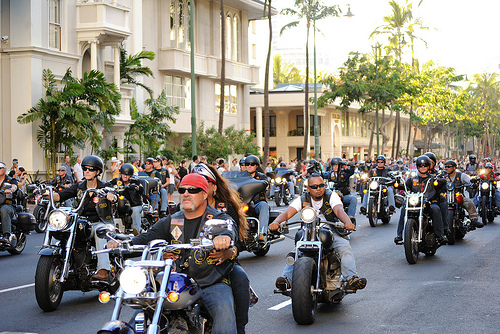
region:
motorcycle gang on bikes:
[32, 137, 496, 332]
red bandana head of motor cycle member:
[176, 170, 210, 191]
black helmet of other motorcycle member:
[79, 154, 104, 169]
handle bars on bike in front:
[94, 240, 219, 252]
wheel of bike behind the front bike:
[291, 255, 316, 324]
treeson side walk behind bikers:
[22, 3, 497, 153]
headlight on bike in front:
[115, 265, 147, 295]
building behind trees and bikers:
[249, 89, 498, 161]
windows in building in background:
[250, 112, 319, 136]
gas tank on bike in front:
[150, 269, 201, 308]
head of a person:
[78, 150, 119, 175]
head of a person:
[174, 152, 226, 212]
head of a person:
[300, 155, 330, 205]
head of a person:
[412, 148, 442, 177]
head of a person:
[240, 146, 270, 177]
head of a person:
[151, 158, 168, 178]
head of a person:
[146, 150, 165, 167]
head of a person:
[52, 154, 77, 176]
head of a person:
[3, 158, 33, 173]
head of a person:
[325, 156, 346, 173]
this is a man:
[132, 156, 259, 318]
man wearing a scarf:
[170, 162, 210, 197]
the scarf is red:
[171, 167, 213, 196]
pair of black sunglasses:
[176, 180, 207, 200]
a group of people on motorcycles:
[0, 114, 491, 321]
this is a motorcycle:
[83, 218, 260, 330]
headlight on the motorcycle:
[108, 250, 163, 310]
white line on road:
[246, 278, 304, 330]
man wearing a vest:
[262, 187, 405, 268]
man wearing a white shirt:
[275, 178, 357, 243]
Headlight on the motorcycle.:
[111, 261, 153, 300]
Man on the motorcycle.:
[262, 165, 376, 330]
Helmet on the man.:
[77, 149, 106, 185]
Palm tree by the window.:
[16, 55, 121, 179]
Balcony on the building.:
[72, 0, 129, 57]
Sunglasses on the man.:
[172, 169, 215, 221]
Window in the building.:
[210, 80, 240, 117]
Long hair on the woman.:
[187, 153, 255, 250]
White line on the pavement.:
[265, 288, 296, 316]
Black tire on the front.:
[283, 248, 325, 327]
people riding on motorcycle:
[97, 115, 482, 325]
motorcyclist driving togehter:
[105, 122, 425, 321]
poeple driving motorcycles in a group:
[164, 134, 435, 271]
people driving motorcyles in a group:
[83, 124, 400, 331]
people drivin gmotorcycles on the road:
[79, 149, 494, 331]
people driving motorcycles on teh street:
[49, 146, 424, 327]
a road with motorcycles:
[171, 144, 486, 329]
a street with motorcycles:
[96, 94, 486, 321]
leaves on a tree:
[32, 56, 177, 152]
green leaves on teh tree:
[44, 56, 151, 161]